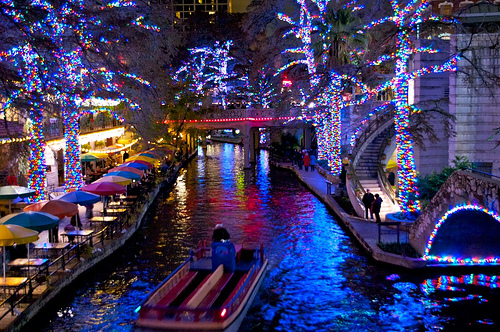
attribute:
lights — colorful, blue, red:
[60, 52, 81, 71]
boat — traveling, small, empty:
[126, 229, 268, 325]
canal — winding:
[47, 136, 364, 332]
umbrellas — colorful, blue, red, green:
[2, 197, 68, 255]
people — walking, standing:
[354, 185, 388, 220]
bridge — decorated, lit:
[155, 99, 305, 170]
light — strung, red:
[158, 113, 296, 122]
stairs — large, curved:
[351, 105, 405, 215]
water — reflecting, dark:
[181, 166, 291, 244]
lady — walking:
[300, 152, 311, 170]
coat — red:
[302, 154, 310, 165]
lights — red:
[395, 57, 404, 68]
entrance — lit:
[406, 165, 499, 287]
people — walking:
[278, 141, 313, 169]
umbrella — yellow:
[0, 218, 39, 268]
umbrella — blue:
[4, 208, 61, 242]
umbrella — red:
[20, 196, 82, 235]